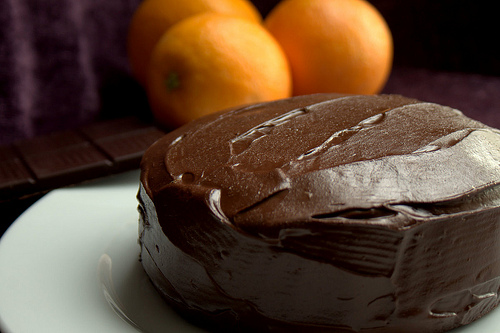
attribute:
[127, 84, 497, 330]
icing — chocolate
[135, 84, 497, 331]
cake — chocolate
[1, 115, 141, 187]
bars — chocolate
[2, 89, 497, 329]
plate — white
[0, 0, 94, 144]
fabric — purple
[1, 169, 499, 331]
plate — white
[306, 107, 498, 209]
frosting — chocolate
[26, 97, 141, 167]
chocolate — smooth 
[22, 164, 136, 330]
plate — white 